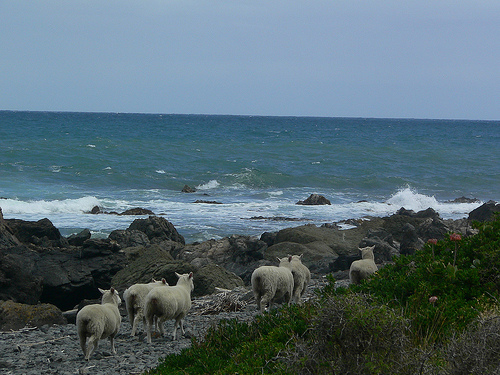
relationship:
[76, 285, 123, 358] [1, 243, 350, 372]
sheep on top of trail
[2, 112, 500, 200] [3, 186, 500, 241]
water in front of shore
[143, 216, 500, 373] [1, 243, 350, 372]
grass on side of trail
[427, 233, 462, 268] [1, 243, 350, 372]
flowers next to trail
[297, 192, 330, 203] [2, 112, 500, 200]
rock inside of water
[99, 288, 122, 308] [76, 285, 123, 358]
head on top of sheep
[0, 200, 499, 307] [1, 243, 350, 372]
rock between trail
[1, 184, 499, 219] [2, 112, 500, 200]
waves on top of water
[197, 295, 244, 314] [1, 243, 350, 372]
sticks on trail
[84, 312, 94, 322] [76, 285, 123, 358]
tail apart of sheep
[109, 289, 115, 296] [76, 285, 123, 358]
ear apart of sheep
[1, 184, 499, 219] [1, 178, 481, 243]
waves covered in foam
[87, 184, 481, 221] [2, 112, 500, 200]
rocks surrouded by water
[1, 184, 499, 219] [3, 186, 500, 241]
waves on top of shore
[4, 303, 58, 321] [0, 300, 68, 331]
moss on top of rock